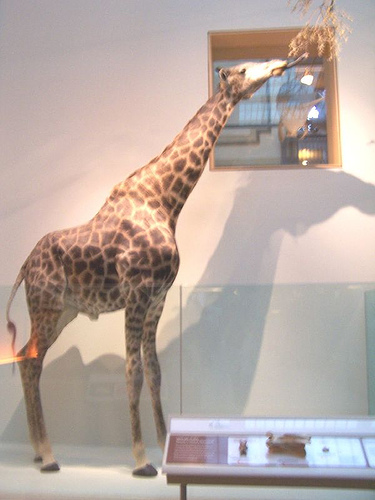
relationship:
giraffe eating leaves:
[12, 47, 328, 471] [283, 1, 349, 63]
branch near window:
[286, 6, 350, 60] [205, 32, 347, 179]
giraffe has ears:
[12, 47, 328, 471] [214, 65, 228, 82]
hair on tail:
[10, 346, 18, 378] [6, 272, 18, 372]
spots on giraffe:
[103, 228, 166, 263] [12, 47, 328, 471]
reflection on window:
[276, 84, 310, 148] [172, 11, 369, 172]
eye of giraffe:
[235, 63, 250, 76] [12, 47, 328, 471]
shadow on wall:
[1, 166, 373, 445] [1, 1, 370, 484]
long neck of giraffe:
[107, 97, 239, 219] [12, 47, 328, 471]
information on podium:
[167, 422, 367, 469] [155, 405, 371, 497]